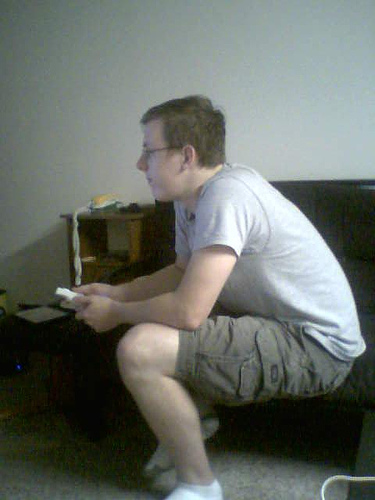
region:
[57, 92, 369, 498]
the man is sitting down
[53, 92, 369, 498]
man holding a game controller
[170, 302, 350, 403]
man is wearing cargo shorts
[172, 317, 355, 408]
cargo shorts are green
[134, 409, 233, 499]
man wearing white socks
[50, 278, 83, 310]
man holding game controller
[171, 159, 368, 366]
man's shirt is white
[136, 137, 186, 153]
man wearing eye glasses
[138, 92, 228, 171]
man's hair is brown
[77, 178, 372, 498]
the couch is black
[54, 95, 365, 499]
the man sitting down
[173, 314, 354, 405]
the shorts on the man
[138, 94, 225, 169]
the hair on the man's head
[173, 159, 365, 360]
the shirt on the man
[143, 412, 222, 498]
the socks on the man's feet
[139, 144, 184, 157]
the glasses on the man's face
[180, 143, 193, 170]
the ear on the man's head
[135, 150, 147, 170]
the nose on the man's face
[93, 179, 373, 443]
the couch the man is sitting on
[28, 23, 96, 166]
a light grey wall.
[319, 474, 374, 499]
a piece of white cord.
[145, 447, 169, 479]
a man is wearing white and grey socks.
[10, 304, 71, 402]
a black and white stand.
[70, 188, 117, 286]
a yellow and white land line phone.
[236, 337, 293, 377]
a man is wearing green shorts.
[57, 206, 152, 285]
a light brown stand with shelfs.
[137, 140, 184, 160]
a man is wearing glasses.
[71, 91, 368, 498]
A man sitting down.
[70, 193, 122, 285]
A white corded telephone.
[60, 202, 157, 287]
A wooden piece of furntiture.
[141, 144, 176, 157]
A pair of glasses.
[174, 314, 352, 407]
A khaki pair of shorts.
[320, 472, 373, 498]
A white colored wire.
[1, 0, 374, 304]
A white colored wall.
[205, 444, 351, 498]
Some tan color carpet.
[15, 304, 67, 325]
White piece of paper.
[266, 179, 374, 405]
A dark colored futon.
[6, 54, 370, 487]
this is a man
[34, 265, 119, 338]
this is a remote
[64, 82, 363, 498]
man holding a remote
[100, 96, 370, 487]
man is sitting down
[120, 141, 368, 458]
the sofa is black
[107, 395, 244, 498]
man wearing white socks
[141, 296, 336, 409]
man wearing green shorts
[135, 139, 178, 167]
a pair of eyeglasses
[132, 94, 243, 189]
man has brown hair